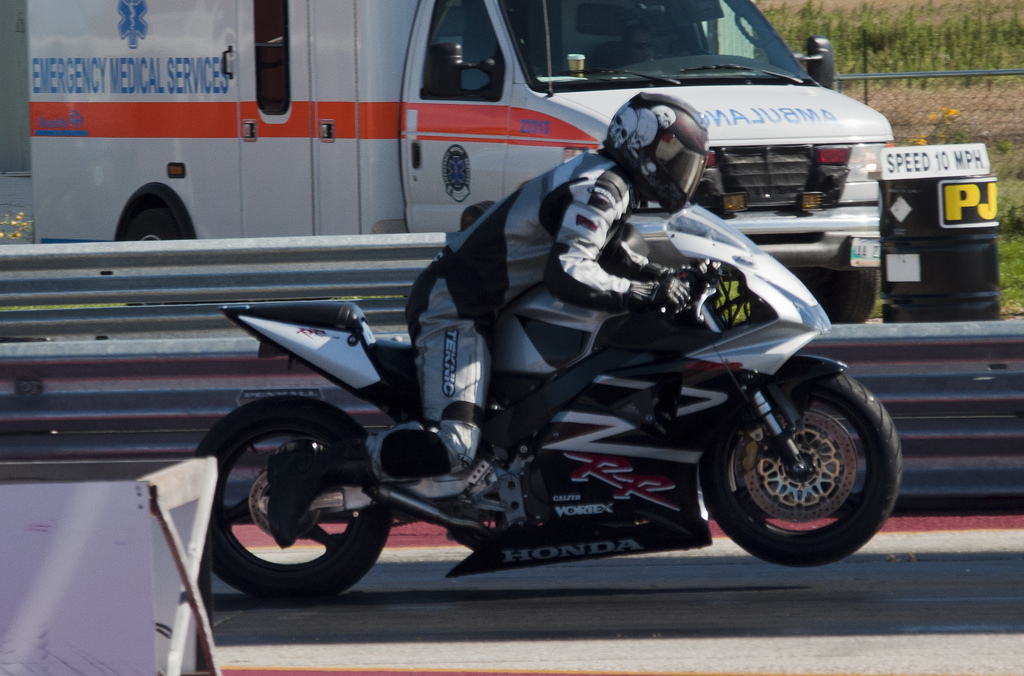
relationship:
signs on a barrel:
[867, 137, 1002, 192] [884, 161, 1012, 317]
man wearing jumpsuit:
[276, 90, 726, 544] [375, 159, 652, 481]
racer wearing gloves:
[265, 83, 704, 546] [624, 254, 709, 311]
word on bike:
[501, 535, 644, 562] [196, 202, 899, 604]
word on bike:
[548, 502, 628, 518] [196, 202, 899, 604]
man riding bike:
[276, 90, 726, 544] [196, 202, 899, 604]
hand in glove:
[630, 282, 691, 311] [628, 276, 695, 307]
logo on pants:
[435, 325, 462, 399] [277, 269, 489, 535]